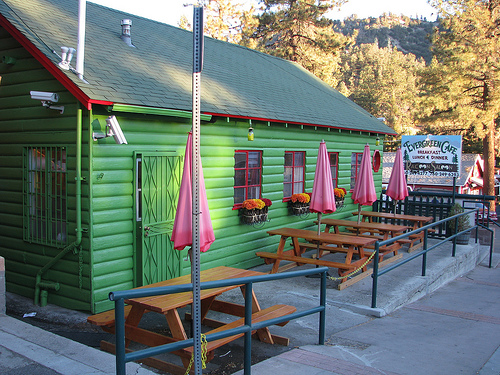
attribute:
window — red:
[232, 147, 268, 207]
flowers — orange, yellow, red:
[230, 191, 277, 211]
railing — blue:
[110, 258, 339, 372]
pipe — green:
[30, 100, 99, 316]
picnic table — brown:
[271, 225, 379, 287]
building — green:
[36, 53, 311, 233]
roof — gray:
[97, 35, 269, 94]